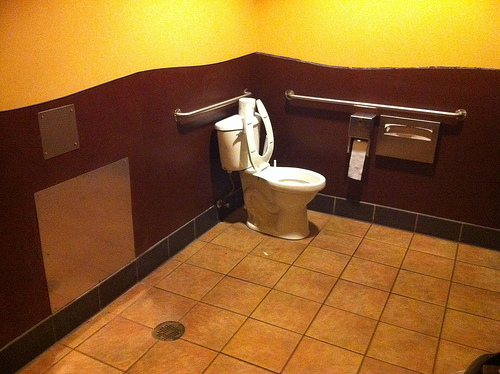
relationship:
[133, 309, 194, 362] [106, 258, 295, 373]
drain in ground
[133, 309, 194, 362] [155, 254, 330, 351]
drain in floor